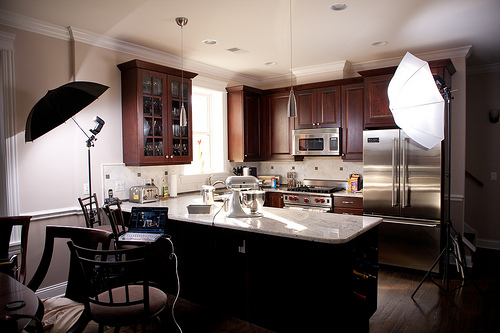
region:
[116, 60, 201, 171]
glass fronted cabinet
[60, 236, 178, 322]
chair with curved back and upholstered seat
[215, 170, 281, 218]
Mixer on a white counter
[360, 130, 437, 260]
stainless steel fridge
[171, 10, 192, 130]
light hanging from ceiling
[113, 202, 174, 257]
laptop on a chair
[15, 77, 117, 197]
Lighting umbrella reflecting light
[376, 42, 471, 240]
lighting umbrella diffusing light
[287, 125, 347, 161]
built in microwave above stove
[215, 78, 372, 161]
Dark wood cabinets with round knobs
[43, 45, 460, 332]
a kitchen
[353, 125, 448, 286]
the refrigerator is silver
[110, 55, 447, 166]
the cabinets are brown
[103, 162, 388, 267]
the counter top is marble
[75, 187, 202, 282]
a laptop is sitting on a chair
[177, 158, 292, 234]
a stand mixer is on the counter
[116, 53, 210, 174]
the cabinet has glass windows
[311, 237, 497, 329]
the floor is wooden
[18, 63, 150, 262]
the light has an umbrella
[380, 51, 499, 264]
the umbrella light is white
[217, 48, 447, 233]
setting up for a photo shoot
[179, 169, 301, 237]
mixer and pan on the counter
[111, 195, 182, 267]
laptop resting ona chair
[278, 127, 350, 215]
stainless steel microwave and range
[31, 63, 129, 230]
photo shoot lighting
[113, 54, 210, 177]
glasswear kept in wall cabinet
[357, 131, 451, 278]
clean stainless steel refridgerator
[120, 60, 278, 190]
window view above the sink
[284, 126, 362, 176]
above the stove microwave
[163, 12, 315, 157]
hanging pendant lighting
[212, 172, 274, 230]
white mixer and stainless steel bowl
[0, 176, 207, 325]
four chairs and one laptop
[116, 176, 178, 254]
toaster and laptop computer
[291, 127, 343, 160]
stainless steel microwave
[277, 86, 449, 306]
stainless steel appliances and wood cabinetry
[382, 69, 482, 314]
light source for professional photography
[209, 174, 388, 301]
mixer and electrical cord on white granite counter tops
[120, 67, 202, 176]
wood and glass cabinets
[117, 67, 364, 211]
wood cabinets, toaster, and microwave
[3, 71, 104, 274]
white decorative molding and white walls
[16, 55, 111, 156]
a black lighting umbrella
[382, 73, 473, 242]
a white lighting umbrella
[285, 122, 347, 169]
a stainless steel space saver microwave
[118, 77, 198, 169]
wood and glass mounted china cabinet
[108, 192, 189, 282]
a laptop computer on a chair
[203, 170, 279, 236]
an electric mixer on a white countertop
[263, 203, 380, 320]
black cabinets with white granite countertops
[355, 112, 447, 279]
a stainless steel french door refridgerator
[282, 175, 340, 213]
a stainless steel gas range with red dials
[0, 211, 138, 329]
a wooden table and dining chairs